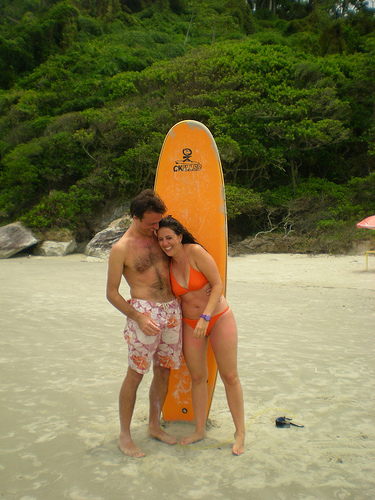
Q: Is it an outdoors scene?
A: Yes, it is outdoors.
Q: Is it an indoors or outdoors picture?
A: It is outdoors.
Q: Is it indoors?
A: No, it is outdoors.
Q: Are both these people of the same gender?
A: No, they are both male and female.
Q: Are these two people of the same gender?
A: No, they are both male and female.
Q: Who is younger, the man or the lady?
A: The man is younger than the lady.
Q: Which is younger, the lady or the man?
A: The man is younger than the lady.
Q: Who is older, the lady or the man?
A: The lady is older than the man.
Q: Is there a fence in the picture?
A: No, there are no fences.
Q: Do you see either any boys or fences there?
A: No, there are no fences or boys.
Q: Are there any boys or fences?
A: No, there are no fences or boys.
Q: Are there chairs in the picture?
A: No, there are no chairs.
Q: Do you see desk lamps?
A: No, there are no desk lamps.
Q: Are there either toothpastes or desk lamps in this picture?
A: No, there are no desk lamps or toothpastes.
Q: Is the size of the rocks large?
A: Yes, the rocks are large.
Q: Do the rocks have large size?
A: Yes, the rocks are large.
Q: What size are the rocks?
A: The rocks are large.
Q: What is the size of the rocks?
A: The rocks are large.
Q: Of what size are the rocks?
A: The rocks are large.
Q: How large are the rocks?
A: The rocks are large.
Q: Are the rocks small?
A: No, the rocks are large.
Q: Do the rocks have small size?
A: No, the rocks are large.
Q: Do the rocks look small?
A: No, the rocks are large.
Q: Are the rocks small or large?
A: The rocks are large.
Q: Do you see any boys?
A: No, there are no boys.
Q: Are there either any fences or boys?
A: No, there are no boys or fences.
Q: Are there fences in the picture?
A: No, there are no fences.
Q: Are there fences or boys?
A: No, there are no fences or boys.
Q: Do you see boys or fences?
A: No, there are no fences or boys.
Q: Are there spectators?
A: No, there are no spectators.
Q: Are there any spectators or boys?
A: No, there are no spectators or boys.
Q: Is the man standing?
A: Yes, the man is standing.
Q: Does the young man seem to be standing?
A: Yes, the man is standing.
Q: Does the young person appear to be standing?
A: Yes, the man is standing.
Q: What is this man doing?
A: The man is standing.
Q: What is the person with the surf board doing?
A: The man is standing.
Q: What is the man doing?
A: The man is standing.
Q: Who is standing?
A: The man is standing.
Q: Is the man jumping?
A: No, the man is standing.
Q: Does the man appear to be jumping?
A: No, the man is standing.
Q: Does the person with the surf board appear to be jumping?
A: No, the man is standing.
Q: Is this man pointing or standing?
A: The man is standing.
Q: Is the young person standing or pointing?
A: The man is standing.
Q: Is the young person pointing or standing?
A: The man is standing.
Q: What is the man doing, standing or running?
A: The man is standing.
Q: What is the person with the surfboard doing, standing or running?
A: The man is standing.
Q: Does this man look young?
A: Yes, the man is young.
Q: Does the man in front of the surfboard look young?
A: Yes, the man is young.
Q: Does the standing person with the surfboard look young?
A: Yes, the man is young.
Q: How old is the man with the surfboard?
A: The man is young.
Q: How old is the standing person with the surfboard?
A: The man is young.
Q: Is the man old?
A: No, the man is young.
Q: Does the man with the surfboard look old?
A: No, the man is young.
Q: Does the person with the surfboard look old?
A: No, the man is young.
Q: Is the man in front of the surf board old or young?
A: The man is young.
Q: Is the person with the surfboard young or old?
A: The man is young.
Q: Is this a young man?
A: Yes, this is a young man.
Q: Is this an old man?
A: No, this is a young man.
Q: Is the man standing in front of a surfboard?
A: Yes, the man is standing in front of a surfboard.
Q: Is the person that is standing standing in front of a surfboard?
A: Yes, the man is standing in front of a surfboard.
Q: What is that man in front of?
A: The man is in front of the surfboard.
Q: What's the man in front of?
A: The man is in front of the surfboard.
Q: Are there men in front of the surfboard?
A: Yes, there is a man in front of the surfboard.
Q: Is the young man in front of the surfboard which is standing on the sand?
A: Yes, the man is in front of the surfboard.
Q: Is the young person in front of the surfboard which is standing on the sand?
A: Yes, the man is in front of the surfboard.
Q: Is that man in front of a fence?
A: No, the man is in front of the surfboard.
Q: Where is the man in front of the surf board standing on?
A: The man is standing on the sand.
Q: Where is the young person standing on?
A: The man is standing on the sand.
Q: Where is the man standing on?
A: The man is standing on the sand.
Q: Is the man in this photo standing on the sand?
A: Yes, the man is standing on the sand.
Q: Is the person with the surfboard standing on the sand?
A: Yes, the man is standing on the sand.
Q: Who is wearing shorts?
A: The man is wearing shorts.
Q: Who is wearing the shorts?
A: The man is wearing shorts.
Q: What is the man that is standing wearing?
A: The man is wearing shorts.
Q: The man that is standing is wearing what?
A: The man is wearing shorts.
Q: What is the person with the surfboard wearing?
A: The man is wearing shorts.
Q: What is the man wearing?
A: The man is wearing shorts.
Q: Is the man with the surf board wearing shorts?
A: Yes, the man is wearing shorts.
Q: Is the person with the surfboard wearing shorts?
A: Yes, the man is wearing shorts.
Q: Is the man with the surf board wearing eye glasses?
A: No, the man is wearing shorts.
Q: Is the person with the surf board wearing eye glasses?
A: No, the man is wearing shorts.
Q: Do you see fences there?
A: No, there are no fences.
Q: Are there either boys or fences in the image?
A: No, there are no fences or boys.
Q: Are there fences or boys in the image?
A: No, there are no fences or boys.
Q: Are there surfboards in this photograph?
A: Yes, there is a surfboard.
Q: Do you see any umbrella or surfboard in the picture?
A: Yes, there is a surfboard.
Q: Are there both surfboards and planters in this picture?
A: No, there is a surfboard but no planters.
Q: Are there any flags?
A: No, there are no flags.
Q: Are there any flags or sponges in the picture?
A: No, there are no flags or sponges.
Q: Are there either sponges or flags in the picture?
A: No, there are no flags or sponges.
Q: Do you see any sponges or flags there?
A: No, there are no flags or sponges.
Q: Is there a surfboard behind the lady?
A: Yes, there is a surfboard behind the lady.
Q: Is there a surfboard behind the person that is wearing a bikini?
A: Yes, there is a surfboard behind the lady.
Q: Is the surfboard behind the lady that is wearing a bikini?
A: Yes, the surfboard is behind the lady.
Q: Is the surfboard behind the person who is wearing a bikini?
A: Yes, the surfboard is behind the lady.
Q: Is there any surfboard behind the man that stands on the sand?
A: Yes, there is a surfboard behind the man.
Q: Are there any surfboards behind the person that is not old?
A: Yes, there is a surfboard behind the man.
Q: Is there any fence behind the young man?
A: No, there is a surfboard behind the man.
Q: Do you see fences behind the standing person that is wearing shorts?
A: No, there is a surfboard behind the man.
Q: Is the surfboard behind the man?
A: Yes, the surfboard is behind the man.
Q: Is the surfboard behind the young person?
A: Yes, the surfboard is behind the man.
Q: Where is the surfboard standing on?
A: The surfboard is standing on the sand.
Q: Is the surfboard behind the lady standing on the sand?
A: Yes, the surfboard is standing on the sand.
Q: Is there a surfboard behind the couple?
A: Yes, there is a surfboard behind the couple.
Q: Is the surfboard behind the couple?
A: Yes, the surfboard is behind the couple.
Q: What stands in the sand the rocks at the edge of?
A: The surfboard stands in the sand.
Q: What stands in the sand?
A: The surfboard stands in the sand.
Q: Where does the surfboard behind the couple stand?
A: The surf board stands in the sand.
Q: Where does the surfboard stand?
A: The surf board stands in the sand.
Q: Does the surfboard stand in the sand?
A: Yes, the surfboard stands in the sand.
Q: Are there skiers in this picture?
A: No, there are no skiers.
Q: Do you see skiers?
A: No, there are no skiers.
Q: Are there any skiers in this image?
A: No, there are no skiers.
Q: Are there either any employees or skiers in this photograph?
A: No, there are no skiers or employees.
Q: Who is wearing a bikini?
A: The lady is wearing a bikini.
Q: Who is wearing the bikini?
A: The lady is wearing a bikini.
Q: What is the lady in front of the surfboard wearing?
A: The lady is wearing a bikini.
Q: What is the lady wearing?
A: The lady is wearing a bikini.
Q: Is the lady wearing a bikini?
A: Yes, the lady is wearing a bikini.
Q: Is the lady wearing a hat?
A: No, the lady is wearing a bikini.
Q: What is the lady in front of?
A: The lady is in front of the surfboard.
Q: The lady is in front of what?
A: The lady is in front of the surfboard.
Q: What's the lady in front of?
A: The lady is in front of the surfboard.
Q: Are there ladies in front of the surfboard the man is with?
A: Yes, there is a lady in front of the surfboard.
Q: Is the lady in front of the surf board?
A: Yes, the lady is in front of the surf board.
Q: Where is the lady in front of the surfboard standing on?
A: The lady is standing on the sand.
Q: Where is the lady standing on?
A: The lady is standing on the sand.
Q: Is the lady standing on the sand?
A: Yes, the lady is standing on the sand.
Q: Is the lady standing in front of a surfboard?
A: Yes, the lady is standing in front of a surfboard.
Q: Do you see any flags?
A: No, there are no flags.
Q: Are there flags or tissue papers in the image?
A: No, there are no flags or tissue papers.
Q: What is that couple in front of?
A: The couple is in front of the surfboard.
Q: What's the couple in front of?
A: The couple is in front of the surfboard.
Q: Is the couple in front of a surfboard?
A: Yes, the couple is in front of a surfboard.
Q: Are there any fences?
A: No, there are no fences.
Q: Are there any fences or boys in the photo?
A: No, there are no fences or boys.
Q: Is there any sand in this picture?
A: Yes, there is sand.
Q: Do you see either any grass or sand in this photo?
A: Yes, there is sand.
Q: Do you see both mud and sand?
A: No, there is sand but no mud.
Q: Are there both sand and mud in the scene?
A: No, there is sand but no mud.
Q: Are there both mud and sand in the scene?
A: No, there is sand but no mud.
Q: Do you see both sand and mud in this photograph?
A: No, there is sand but no mud.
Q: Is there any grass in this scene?
A: No, there is no grass.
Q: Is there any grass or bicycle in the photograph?
A: No, there are no grass or bicycles.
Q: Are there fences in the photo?
A: No, there are no fences.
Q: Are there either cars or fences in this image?
A: No, there are no fences or cars.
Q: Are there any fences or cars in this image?
A: No, there are no fences or cars.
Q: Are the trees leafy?
A: Yes, the trees are leafy.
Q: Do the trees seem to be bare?
A: No, the trees are leafy.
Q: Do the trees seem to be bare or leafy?
A: The trees are leafy.